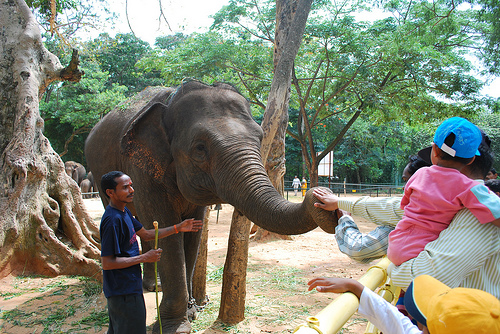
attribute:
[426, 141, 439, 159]
ear — small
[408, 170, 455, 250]
outfit — pink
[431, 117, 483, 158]
cap — yellow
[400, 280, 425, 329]
stripe — blue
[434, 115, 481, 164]
hat — blue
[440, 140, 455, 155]
snap — white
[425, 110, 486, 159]
hat — blue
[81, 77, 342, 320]
elephant — grey, extending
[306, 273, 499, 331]
child — young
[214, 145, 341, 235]
trunk — long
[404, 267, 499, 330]
hat — yellow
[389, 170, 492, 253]
shirt — pink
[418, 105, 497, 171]
baseball cap — blue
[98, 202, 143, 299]
t shirt — navy blue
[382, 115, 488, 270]
child — young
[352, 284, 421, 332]
shirt — white